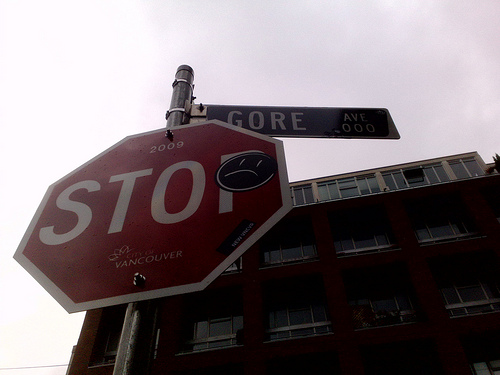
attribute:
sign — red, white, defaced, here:
[13, 118, 295, 315]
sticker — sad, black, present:
[216, 150, 278, 192]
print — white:
[39, 150, 264, 246]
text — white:
[114, 249, 182, 267]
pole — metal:
[124, 64, 196, 375]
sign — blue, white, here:
[207, 104, 401, 140]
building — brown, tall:
[65, 150, 500, 374]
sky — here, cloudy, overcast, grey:
[1, 0, 499, 374]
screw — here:
[165, 129, 173, 138]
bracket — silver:
[166, 108, 188, 119]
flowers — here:
[354, 305, 378, 328]